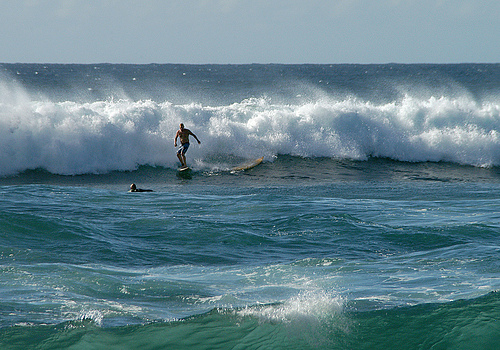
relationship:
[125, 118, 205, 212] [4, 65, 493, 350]
people in water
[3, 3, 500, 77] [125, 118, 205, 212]
sky above people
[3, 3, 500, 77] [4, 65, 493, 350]
sky above water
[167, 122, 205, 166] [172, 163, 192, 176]
man on board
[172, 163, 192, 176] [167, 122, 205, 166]
board under man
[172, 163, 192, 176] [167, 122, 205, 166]
board below man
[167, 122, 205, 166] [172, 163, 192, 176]
man above board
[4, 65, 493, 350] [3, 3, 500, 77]
water below sky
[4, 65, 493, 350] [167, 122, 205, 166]
water beside man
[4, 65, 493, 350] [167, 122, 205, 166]
water close to man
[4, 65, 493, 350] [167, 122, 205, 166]
water above man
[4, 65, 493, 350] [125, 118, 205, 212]
water above people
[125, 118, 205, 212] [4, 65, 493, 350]
people below water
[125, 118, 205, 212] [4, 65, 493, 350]
people under water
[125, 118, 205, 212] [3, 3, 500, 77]
people under sky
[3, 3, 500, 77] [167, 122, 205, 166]
sky above man